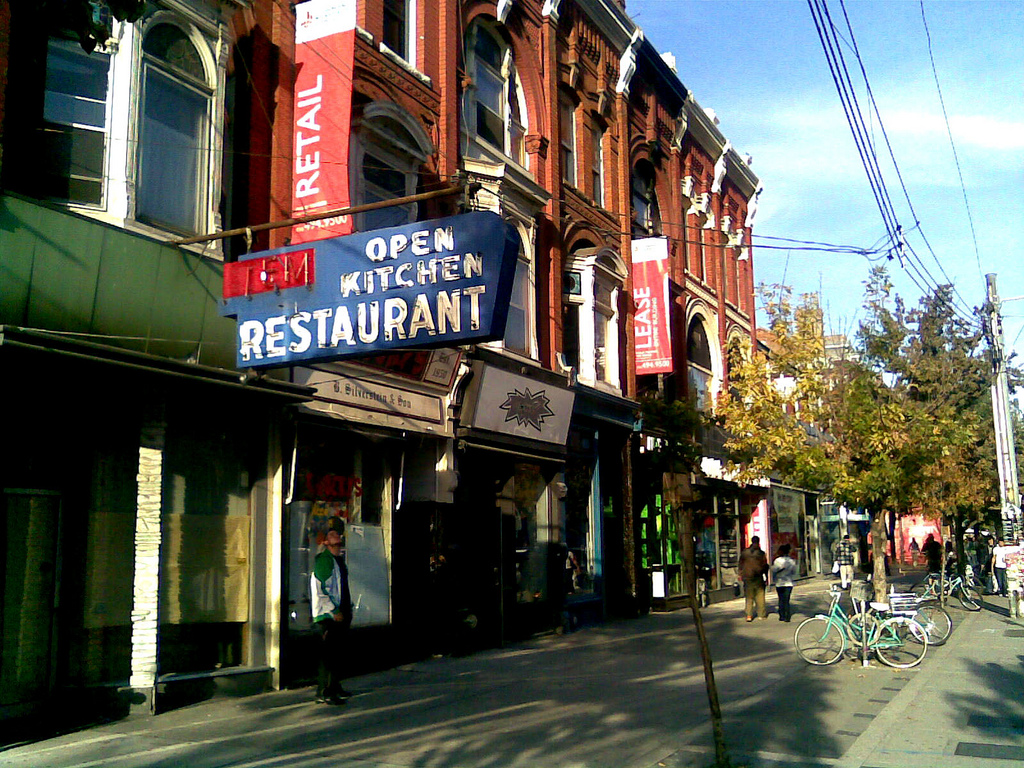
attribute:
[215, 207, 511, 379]
sign — blue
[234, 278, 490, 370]
sign — blue